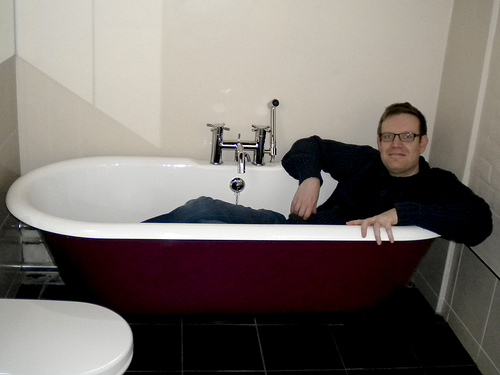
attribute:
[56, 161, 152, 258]
tub — red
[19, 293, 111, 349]
toilet — white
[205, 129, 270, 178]
faucet — silver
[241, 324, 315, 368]
floor — black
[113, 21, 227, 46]
wall — white